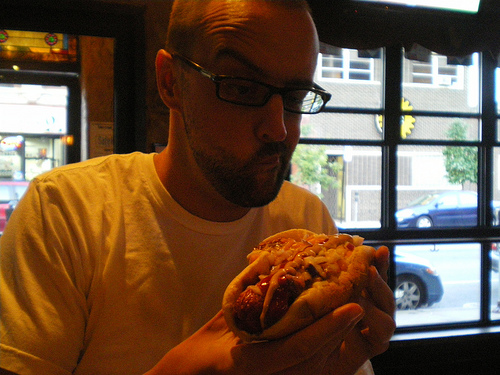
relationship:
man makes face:
[32, 32, 368, 363] [154, 42, 348, 240]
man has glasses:
[32, 32, 368, 363] [170, 51, 332, 120]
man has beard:
[32, 32, 368, 363] [204, 156, 286, 216]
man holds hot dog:
[32, 32, 368, 363] [222, 227, 389, 332]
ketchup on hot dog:
[235, 242, 343, 304] [222, 227, 389, 332]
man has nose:
[32, 32, 368, 363] [265, 92, 288, 150]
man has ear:
[32, 32, 368, 363] [162, 46, 184, 119]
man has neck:
[32, 32, 368, 363] [134, 117, 245, 245]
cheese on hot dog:
[267, 227, 339, 299] [222, 227, 389, 332]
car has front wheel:
[376, 254, 451, 319] [392, 274, 420, 311]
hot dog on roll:
[222, 227, 389, 332] [209, 251, 269, 348]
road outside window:
[411, 241, 478, 308] [320, 38, 487, 318]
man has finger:
[32, 32, 368, 363] [275, 304, 361, 365]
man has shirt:
[32, 32, 368, 363] [17, 140, 331, 365]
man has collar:
[32, 32, 368, 363] [147, 157, 250, 226]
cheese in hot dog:
[267, 227, 339, 299] [222, 227, 389, 332]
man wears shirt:
[32, 32, 368, 363] [17, 140, 331, 365]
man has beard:
[32, 32, 368, 363] [197, 143, 293, 208]